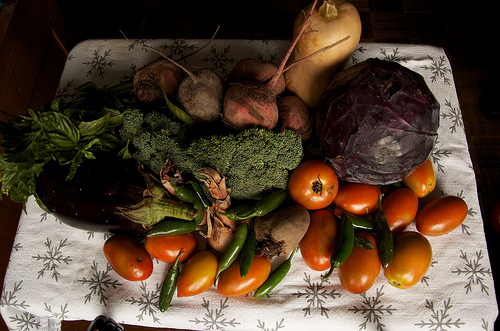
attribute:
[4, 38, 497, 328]
cloth — white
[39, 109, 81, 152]
basil — leafy, green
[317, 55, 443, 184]
cabbage — purple, red, head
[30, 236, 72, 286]
snowflake — silver, gray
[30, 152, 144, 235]
bowl — black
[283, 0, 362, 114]
gourd — brown, tall, vegetable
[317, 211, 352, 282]
pepper — long, vegetable, green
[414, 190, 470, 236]
tomatoe — orange, vegerable, red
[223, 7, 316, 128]
beet — red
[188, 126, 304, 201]
broccoli — green, vegetable